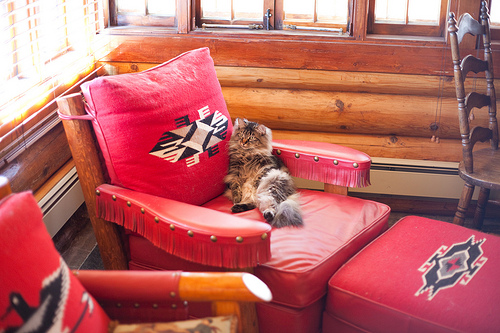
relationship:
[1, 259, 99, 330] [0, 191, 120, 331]
bird design on cushion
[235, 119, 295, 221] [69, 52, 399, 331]
cat lying in chair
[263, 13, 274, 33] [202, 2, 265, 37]
latch on windowsill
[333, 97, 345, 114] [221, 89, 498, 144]
dark spot on log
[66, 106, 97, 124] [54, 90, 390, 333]
strap on chair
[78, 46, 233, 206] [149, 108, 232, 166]
cushion with design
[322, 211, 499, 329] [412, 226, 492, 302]
ottoman with design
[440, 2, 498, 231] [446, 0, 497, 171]
wood chair with chair back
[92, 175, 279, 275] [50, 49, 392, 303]
fringe on arm of chair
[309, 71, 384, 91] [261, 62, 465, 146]
knoll in wood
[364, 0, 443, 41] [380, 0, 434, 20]
wooden frame on window